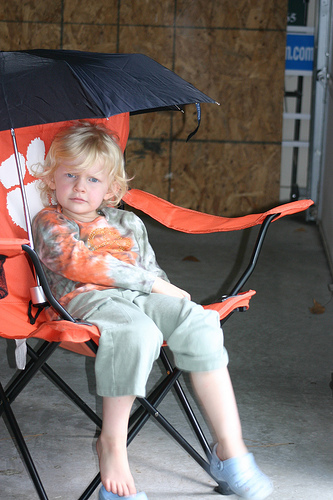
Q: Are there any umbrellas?
A: Yes, there is an umbrella.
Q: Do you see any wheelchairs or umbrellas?
A: Yes, there is an umbrella.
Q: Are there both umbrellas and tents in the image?
A: No, there is an umbrella but no tents.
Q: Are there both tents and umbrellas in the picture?
A: No, there is an umbrella but no tents.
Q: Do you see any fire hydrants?
A: No, there are no fire hydrants.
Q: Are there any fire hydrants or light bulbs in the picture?
A: No, there are no fire hydrants or light bulbs.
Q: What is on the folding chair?
A: The umbrella is on the folding chair.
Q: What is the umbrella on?
A: The umbrella is on the folding chair.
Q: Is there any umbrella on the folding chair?
A: Yes, there is an umbrella on the folding chair.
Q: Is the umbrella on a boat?
A: No, the umbrella is on the folding chair.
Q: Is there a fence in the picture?
A: No, there are no fences.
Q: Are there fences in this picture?
A: No, there are no fences.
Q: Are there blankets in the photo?
A: No, there are no blankets.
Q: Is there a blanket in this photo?
A: No, there are no blankets.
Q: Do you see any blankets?
A: No, there are no blankets.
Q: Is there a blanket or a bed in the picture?
A: No, there are no blankets or beds.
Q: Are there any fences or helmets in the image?
A: No, there are no fences or helmets.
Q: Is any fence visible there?
A: No, there are no fences.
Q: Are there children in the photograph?
A: Yes, there is a child.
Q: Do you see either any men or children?
A: Yes, there is a child.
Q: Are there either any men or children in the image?
A: Yes, there is a child.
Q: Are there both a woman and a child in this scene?
A: No, there is a child but no women.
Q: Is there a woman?
A: No, there are no women.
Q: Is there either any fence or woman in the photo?
A: No, there are no women or fences.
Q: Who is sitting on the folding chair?
A: The kid is sitting on the folding chair.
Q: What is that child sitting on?
A: The child is sitting on the folding chair.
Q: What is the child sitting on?
A: The child is sitting on the folding chair.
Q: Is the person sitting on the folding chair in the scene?
A: Yes, the kid is sitting on the folding chair.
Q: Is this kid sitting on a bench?
A: No, the kid is sitting on the folding chair.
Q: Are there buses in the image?
A: No, there are no buses.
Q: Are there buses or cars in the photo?
A: No, there are no buses or cars.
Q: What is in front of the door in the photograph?
A: The sign is in front of the door.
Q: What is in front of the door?
A: The sign is in front of the door.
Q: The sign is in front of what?
A: The sign is in front of the door.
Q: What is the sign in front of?
A: The sign is in front of the door.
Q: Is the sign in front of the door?
A: Yes, the sign is in front of the door.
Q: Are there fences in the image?
A: No, there are no fences.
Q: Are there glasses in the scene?
A: No, there are no glasses.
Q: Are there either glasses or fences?
A: No, there are no glasses or fences.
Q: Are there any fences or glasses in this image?
A: No, there are no glasses or fences.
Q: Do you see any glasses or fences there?
A: No, there are no glasses or fences.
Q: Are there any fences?
A: No, there are no fences.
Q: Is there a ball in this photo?
A: No, there are no balls.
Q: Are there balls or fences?
A: No, there are no balls or fences.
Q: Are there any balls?
A: No, there are no balls.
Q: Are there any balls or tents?
A: No, there are no balls or tents.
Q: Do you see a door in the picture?
A: Yes, there is a door.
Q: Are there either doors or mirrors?
A: Yes, there is a door.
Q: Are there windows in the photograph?
A: No, there are no windows.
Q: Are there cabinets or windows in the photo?
A: No, there are no windows or cabinets.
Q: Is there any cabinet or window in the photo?
A: No, there are no windows or cabinets.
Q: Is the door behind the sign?
A: Yes, the door is behind the sign.